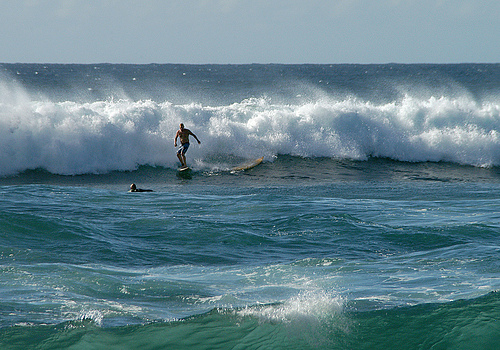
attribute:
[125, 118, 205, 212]
people — swimming, surfing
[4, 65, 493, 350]
water — big, wavy, white, roaring, rough, blue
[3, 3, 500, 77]
sky — grey, big, huge, clear, blue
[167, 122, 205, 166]
man — white, standing, shirtless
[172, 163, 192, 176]
board — small